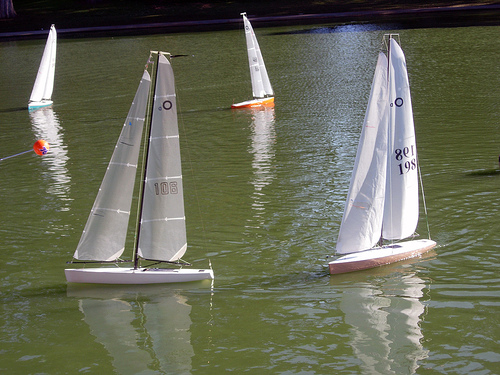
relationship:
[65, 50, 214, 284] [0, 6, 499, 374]
toy boat on water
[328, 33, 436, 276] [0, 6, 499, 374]
toy boat on water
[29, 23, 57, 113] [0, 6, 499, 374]
toy boat on water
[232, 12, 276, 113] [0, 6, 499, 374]
toy boat on water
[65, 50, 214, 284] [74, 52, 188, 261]
toy boat has a sail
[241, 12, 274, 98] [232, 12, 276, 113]
sail on toy boat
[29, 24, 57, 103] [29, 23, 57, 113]
sail on toy boat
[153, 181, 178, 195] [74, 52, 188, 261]
numbers on sail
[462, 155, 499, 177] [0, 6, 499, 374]
shadow on water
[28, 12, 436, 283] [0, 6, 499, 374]
toy boats are on water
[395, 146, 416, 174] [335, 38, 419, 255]
numbers on sail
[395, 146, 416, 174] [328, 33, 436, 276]
numbers on toy boat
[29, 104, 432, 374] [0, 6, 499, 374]
reflection in water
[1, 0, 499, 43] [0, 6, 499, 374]
ledge near water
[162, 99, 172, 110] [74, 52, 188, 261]
circle on sail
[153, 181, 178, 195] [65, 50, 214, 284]
numbers on toy boat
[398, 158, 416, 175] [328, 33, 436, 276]
198 on toy boat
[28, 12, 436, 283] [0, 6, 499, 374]
toy boats on water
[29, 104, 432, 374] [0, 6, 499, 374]
reflection on water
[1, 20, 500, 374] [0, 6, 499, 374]
sunlight reflecting on water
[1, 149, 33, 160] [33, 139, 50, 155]
string attached to fishing bobber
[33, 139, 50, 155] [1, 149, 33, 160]
fishing bobber attached to string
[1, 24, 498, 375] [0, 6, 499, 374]
ripples in water